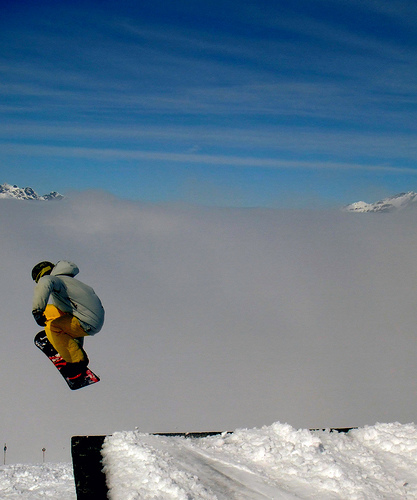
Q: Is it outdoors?
A: Yes, it is outdoors.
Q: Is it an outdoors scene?
A: Yes, it is outdoors.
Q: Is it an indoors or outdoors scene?
A: It is outdoors.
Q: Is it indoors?
A: No, it is outdoors.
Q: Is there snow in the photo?
A: Yes, there is snow.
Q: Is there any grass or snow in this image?
A: Yes, there is snow.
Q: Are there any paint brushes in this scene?
A: No, there are no paint brushes.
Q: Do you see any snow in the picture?
A: Yes, there is snow.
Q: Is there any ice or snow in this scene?
A: Yes, there is snow.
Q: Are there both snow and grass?
A: No, there is snow but no grass.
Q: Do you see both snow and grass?
A: No, there is snow but no grass.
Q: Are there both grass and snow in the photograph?
A: No, there is snow but no grass.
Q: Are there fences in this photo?
A: No, there are no fences.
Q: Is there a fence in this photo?
A: No, there are no fences.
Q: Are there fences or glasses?
A: No, there are no fences or glasses.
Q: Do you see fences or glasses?
A: No, there are no fences or glasses.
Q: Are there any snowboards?
A: Yes, there is a snowboard.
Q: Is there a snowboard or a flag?
A: Yes, there is a snowboard.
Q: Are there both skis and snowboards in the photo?
A: No, there is a snowboard but no skis.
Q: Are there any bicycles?
A: No, there are no bicycles.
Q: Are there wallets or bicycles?
A: No, there are no bicycles or wallets.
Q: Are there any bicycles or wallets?
A: No, there are no bicycles or wallets.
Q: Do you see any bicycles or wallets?
A: No, there are no bicycles or wallets.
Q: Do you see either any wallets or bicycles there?
A: No, there are no bicycles or wallets.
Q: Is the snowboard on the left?
A: Yes, the snowboard is on the left of the image.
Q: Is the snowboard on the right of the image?
A: No, the snowboard is on the left of the image.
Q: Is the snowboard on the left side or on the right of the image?
A: The snowboard is on the left of the image.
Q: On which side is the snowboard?
A: The snowboard is on the left of the image.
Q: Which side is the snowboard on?
A: The snowboard is on the left of the image.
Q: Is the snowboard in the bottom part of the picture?
A: Yes, the snowboard is in the bottom of the image.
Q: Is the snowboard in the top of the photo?
A: No, the snowboard is in the bottom of the image.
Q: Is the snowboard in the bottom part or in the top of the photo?
A: The snowboard is in the bottom of the image.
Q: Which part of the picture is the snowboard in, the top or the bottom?
A: The snowboard is in the bottom of the image.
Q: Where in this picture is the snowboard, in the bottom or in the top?
A: The snowboard is in the bottom of the image.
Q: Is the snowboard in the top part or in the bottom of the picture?
A: The snowboard is in the bottom of the image.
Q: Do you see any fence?
A: No, there are no fences.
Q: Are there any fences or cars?
A: No, there are no fences or cars.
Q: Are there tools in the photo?
A: No, there are no tools.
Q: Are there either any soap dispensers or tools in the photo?
A: No, there are no tools or soap dispensers.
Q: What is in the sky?
A: The clouds are in the sky.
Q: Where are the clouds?
A: The clouds are in the sky.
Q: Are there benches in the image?
A: No, there are no benches.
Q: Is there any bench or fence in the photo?
A: No, there are no benches or fences.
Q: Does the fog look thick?
A: Yes, the fog is thick.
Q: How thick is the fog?
A: The fog is thick.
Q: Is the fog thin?
A: No, the fog is thick.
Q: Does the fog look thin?
A: No, the fog is thick.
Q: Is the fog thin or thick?
A: The fog is thick.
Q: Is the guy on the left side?
A: Yes, the guy is on the left of the image.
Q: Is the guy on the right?
A: No, the guy is on the left of the image.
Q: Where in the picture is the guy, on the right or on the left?
A: The guy is on the left of the image.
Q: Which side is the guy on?
A: The guy is on the left of the image.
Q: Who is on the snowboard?
A: The guy is on the snowboard.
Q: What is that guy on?
A: The guy is on the snowboard.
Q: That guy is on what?
A: The guy is on the snowboard.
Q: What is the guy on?
A: The guy is on the snowboard.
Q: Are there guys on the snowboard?
A: Yes, there is a guy on the snowboard.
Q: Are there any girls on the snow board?
A: No, there is a guy on the snow board.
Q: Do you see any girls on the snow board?
A: No, there is a guy on the snow board.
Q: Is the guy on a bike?
A: No, the guy is on the snowboard.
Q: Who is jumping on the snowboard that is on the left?
A: The guy is jumping on the snowboard.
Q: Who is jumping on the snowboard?
A: The guy is jumping on the snowboard.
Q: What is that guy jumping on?
A: The guy is jumping on the snowboard.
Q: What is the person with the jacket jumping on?
A: The guy is jumping on the snowboard.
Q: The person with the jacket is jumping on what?
A: The guy is jumping on the snowboard.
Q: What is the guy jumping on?
A: The guy is jumping on the snowboard.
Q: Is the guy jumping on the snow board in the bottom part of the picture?
A: Yes, the guy is jumping on the snowboard.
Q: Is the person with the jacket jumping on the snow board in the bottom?
A: Yes, the guy is jumping on the snowboard.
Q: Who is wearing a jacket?
A: The guy is wearing a jacket.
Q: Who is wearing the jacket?
A: The guy is wearing a jacket.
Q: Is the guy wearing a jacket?
A: Yes, the guy is wearing a jacket.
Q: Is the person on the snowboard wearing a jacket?
A: Yes, the guy is wearing a jacket.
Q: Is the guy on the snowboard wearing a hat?
A: No, the guy is wearing a jacket.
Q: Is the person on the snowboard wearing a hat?
A: No, the guy is wearing a jacket.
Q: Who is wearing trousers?
A: The guy is wearing trousers.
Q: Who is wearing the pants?
A: The guy is wearing trousers.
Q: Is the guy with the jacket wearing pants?
A: Yes, the guy is wearing pants.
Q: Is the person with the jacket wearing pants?
A: Yes, the guy is wearing pants.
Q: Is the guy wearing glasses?
A: No, the guy is wearing pants.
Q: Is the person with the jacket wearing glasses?
A: No, the guy is wearing pants.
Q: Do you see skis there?
A: No, there are no skis.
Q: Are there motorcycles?
A: No, there are no motorcycles.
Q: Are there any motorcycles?
A: No, there are no motorcycles.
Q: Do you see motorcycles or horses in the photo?
A: No, there are no motorcycles or horses.